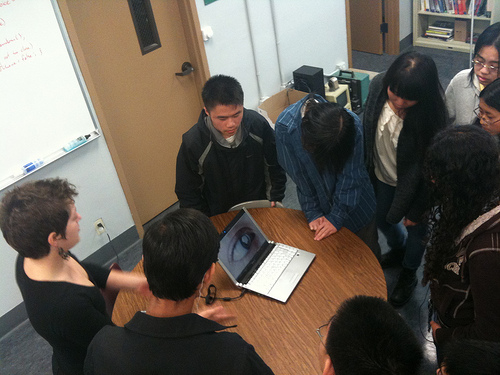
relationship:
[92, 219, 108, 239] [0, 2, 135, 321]
outlet on wall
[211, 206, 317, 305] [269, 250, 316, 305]
laptop has a track pad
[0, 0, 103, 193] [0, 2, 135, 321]
white board mounted on wall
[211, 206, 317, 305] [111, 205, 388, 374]
laptop sitting on table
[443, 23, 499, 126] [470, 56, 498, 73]
kid wearing glasses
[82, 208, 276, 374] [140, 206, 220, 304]
man has a head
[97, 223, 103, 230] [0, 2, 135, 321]
plug plugged into wall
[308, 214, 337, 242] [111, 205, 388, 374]
hands are resting on table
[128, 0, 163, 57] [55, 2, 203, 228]
window in door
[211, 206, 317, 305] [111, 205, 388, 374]
laptop on top of table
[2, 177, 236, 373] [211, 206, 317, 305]
person near laptop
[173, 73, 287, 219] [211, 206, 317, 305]
man next to laptop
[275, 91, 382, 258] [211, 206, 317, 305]
boy near laptop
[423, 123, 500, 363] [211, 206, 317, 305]
person close to laptop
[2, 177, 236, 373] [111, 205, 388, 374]
person standing at table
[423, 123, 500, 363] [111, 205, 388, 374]
person standing next to table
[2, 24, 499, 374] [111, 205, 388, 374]
people standing around table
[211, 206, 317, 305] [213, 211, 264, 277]
laptop has a screen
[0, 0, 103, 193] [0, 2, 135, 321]
white board hanging on wall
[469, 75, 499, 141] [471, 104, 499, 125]
woman wearing eyeglasses